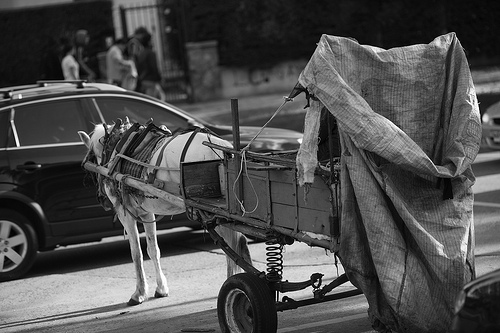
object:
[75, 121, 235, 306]
horse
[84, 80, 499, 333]
cart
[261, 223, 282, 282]
spring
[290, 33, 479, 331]
bag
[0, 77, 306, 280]
car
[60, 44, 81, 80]
people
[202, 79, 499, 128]
sidewalk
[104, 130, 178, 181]
harness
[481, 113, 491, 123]
headlight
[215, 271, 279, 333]
tire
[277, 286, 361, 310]
axle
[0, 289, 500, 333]
shadow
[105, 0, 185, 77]
gate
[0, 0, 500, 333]
picture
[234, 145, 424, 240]
buggy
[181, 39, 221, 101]
can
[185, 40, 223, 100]
garbage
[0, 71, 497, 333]
road